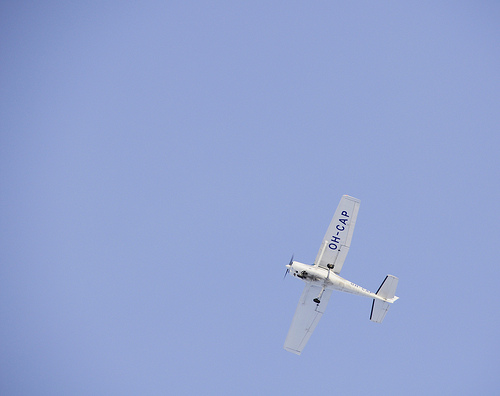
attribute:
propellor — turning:
[277, 250, 302, 289]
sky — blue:
[177, 76, 378, 99]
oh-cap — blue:
[327, 209, 348, 248]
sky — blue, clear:
[0, 0, 498, 394]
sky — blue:
[167, 44, 447, 159]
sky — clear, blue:
[15, 154, 197, 381]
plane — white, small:
[281, 191, 401, 356]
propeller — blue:
[283, 250, 303, 285]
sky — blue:
[69, 13, 490, 176]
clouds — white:
[20, 323, 92, 394]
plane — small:
[257, 190, 425, 352]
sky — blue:
[3, 0, 305, 233]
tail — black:
[370, 272, 398, 322]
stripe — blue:
[362, 279, 387, 319]